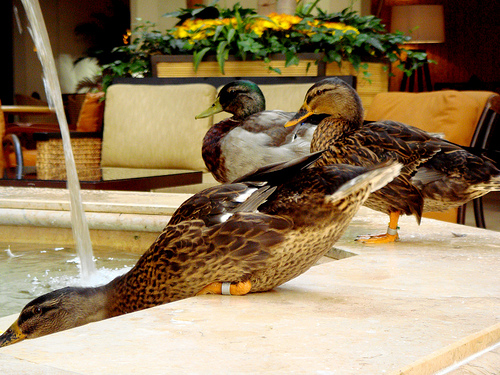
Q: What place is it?
A: It is a pond.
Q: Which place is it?
A: It is a pond.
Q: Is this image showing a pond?
A: Yes, it is showing a pond.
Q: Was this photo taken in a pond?
A: Yes, it was taken in a pond.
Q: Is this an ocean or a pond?
A: It is a pond.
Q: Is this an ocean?
A: No, it is a pond.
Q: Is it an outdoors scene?
A: Yes, it is outdoors.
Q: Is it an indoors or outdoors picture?
A: It is outdoors.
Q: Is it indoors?
A: No, it is outdoors.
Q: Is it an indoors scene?
A: No, it is outdoors.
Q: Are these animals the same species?
A: Yes, all the animals are ducks.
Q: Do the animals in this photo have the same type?
A: Yes, all the animals are ducks.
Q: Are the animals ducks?
A: Yes, all the animals are ducks.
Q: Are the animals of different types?
A: No, all the animals are ducks.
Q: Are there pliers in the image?
A: No, there are no pliers.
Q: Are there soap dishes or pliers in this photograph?
A: No, there are no pliers or soap dishes.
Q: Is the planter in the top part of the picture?
A: Yes, the planter is in the top of the image.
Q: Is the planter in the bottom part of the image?
A: No, the planter is in the top of the image.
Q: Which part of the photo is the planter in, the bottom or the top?
A: The planter is in the top of the image.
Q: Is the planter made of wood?
A: Yes, the planter is made of wood.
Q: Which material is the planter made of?
A: The planter is made of wood.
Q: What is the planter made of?
A: The planter is made of wood.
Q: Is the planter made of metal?
A: No, the planter is made of wood.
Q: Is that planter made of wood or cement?
A: The planter is made of wood.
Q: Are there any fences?
A: No, there are no fences.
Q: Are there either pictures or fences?
A: No, there are no fences or pictures.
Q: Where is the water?
A: The water is on the pond.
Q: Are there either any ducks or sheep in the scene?
A: Yes, there is a duck.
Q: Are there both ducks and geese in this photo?
A: No, there is a duck but no geese.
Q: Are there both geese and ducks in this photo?
A: No, there is a duck but no geese.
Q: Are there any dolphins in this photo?
A: No, there are no dolphins.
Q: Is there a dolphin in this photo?
A: No, there are no dolphins.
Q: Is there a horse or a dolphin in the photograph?
A: No, there are no dolphins or horses.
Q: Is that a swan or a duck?
A: That is a duck.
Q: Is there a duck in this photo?
A: Yes, there is a duck.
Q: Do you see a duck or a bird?
A: Yes, there is a duck.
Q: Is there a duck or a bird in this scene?
A: Yes, there is a duck.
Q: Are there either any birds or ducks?
A: Yes, there is a duck.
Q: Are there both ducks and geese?
A: No, there is a duck but no geese.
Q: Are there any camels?
A: No, there are no camels.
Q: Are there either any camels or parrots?
A: No, there are no camels or parrots.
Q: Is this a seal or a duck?
A: This is a duck.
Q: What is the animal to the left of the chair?
A: The animal is a duck.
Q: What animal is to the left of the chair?
A: The animal is a duck.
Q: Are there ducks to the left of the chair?
A: Yes, there is a duck to the left of the chair.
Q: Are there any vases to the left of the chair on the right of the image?
A: No, there is a duck to the left of the chair.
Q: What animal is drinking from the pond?
A: The duck is drinking from the pond.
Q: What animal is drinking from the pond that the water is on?
A: The animal is a duck.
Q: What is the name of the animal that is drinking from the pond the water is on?
A: The animal is a duck.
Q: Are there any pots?
A: Yes, there is a pot.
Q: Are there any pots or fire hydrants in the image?
A: Yes, there is a pot.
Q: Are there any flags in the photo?
A: No, there are no flags.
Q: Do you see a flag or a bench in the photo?
A: No, there are no flags or benches.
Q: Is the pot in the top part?
A: Yes, the pot is in the top of the image.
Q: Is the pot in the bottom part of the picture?
A: No, the pot is in the top of the image.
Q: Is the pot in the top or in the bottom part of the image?
A: The pot is in the top of the image.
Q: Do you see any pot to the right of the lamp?
A: No, the pot is to the left of the lamp.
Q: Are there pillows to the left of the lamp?
A: No, there is a pot to the left of the lamp.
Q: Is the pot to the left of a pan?
A: No, the pot is to the left of the lamp.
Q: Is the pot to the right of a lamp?
A: No, the pot is to the left of a lamp.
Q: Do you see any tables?
A: Yes, there is a table.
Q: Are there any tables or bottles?
A: Yes, there is a table.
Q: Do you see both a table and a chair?
A: Yes, there are both a table and a chair.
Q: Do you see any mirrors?
A: No, there are no mirrors.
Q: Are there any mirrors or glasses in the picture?
A: No, there are no mirrors or glasses.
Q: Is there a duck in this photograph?
A: Yes, there is a duck.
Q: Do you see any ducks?
A: Yes, there is a duck.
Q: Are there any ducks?
A: Yes, there is a duck.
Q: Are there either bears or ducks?
A: Yes, there is a duck.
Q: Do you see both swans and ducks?
A: No, there is a duck but no swans.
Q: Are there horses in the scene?
A: No, there are no horses.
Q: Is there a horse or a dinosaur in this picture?
A: No, there are no horses or dinosaurs.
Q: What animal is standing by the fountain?
A: The duck is standing by the fountain.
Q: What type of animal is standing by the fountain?
A: The animal is a duck.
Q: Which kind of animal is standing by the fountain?
A: The animal is a duck.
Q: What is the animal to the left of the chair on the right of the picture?
A: The animal is a duck.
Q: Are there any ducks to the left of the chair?
A: Yes, there is a duck to the left of the chair.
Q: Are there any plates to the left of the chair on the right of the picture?
A: No, there is a duck to the left of the chair.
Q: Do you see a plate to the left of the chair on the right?
A: No, there is a duck to the left of the chair.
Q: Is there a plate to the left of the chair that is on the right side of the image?
A: No, there is a duck to the left of the chair.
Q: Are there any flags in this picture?
A: No, there are no flags.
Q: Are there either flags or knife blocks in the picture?
A: No, there are no flags or knife blocks.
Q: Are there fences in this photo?
A: No, there are no fences.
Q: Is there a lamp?
A: Yes, there is a lamp.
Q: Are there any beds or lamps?
A: Yes, there is a lamp.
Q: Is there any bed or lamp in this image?
A: Yes, there is a lamp.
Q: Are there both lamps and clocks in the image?
A: No, there is a lamp but no clocks.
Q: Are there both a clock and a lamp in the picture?
A: No, there is a lamp but no clocks.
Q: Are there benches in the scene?
A: No, there are no benches.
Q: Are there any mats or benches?
A: No, there are no benches or mats.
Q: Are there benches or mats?
A: No, there are no benches or mats.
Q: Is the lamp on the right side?
A: Yes, the lamp is on the right of the image.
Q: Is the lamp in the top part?
A: Yes, the lamp is in the top of the image.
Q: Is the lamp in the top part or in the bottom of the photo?
A: The lamp is in the top of the image.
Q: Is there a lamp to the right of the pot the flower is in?
A: Yes, there is a lamp to the right of the pot.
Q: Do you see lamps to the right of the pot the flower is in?
A: Yes, there is a lamp to the right of the pot.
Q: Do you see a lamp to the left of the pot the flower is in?
A: No, the lamp is to the right of the pot.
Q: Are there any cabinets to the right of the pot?
A: No, there is a lamp to the right of the pot.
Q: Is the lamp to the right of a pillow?
A: No, the lamp is to the right of the pot.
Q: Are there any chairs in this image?
A: Yes, there is a chair.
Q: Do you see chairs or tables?
A: Yes, there is a chair.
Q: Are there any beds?
A: No, there are no beds.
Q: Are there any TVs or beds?
A: No, there are no beds or tvs.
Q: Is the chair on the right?
A: Yes, the chair is on the right of the image.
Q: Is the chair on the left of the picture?
A: No, the chair is on the right of the image.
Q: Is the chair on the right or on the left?
A: The chair is on the right of the image.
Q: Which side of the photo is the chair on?
A: The chair is on the right of the image.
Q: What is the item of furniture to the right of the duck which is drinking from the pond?
A: The piece of furniture is a chair.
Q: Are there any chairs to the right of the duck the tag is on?
A: Yes, there is a chair to the right of the duck.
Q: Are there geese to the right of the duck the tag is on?
A: No, there is a chair to the right of the duck.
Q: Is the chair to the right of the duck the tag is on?
A: Yes, the chair is to the right of the duck.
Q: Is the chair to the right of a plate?
A: No, the chair is to the right of the duck.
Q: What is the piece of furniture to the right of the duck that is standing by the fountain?
A: The piece of furniture is a chair.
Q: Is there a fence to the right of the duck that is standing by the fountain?
A: No, there is a chair to the right of the duck.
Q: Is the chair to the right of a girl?
A: No, the chair is to the right of the duck.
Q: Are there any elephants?
A: No, there are no elephants.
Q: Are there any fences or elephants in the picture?
A: No, there are no elephants or fences.